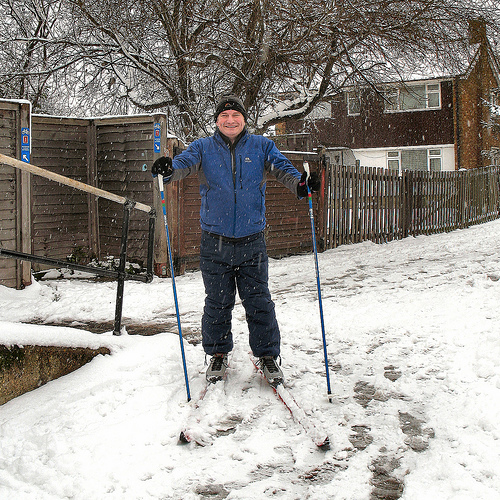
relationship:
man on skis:
[150, 96, 319, 384] [181, 383, 332, 449]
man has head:
[150, 96, 319, 384] [214, 94, 247, 136]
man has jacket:
[150, 96, 319, 384] [167, 131, 304, 234]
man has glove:
[150, 96, 319, 384] [150, 156, 177, 179]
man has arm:
[150, 96, 319, 384] [153, 139, 207, 184]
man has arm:
[150, 96, 319, 384] [264, 136, 324, 200]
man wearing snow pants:
[150, 96, 319, 384] [197, 229, 283, 358]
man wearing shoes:
[150, 96, 319, 384] [203, 353, 284, 384]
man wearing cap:
[150, 96, 319, 384] [214, 95, 250, 120]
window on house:
[385, 82, 439, 111] [271, 16, 500, 205]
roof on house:
[282, 38, 500, 87] [271, 16, 500, 205]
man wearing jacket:
[150, 96, 319, 384] [167, 131, 304, 234]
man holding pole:
[150, 96, 319, 384] [302, 160, 334, 407]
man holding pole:
[150, 96, 319, 384] [155, 174, 193, 405]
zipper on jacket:
[232, 180, 239, 238] [167, 131, 304, 234]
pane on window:
[399, 86, 426, 109] [385, 82, 439, 111]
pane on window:
[429, 92, 439, 108] [385, 82, 439, 111]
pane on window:
[385, 95, 395, 109] [385, 82, 439, 111]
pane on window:
[402, 150, 430, 175] [387, 146, 444, 171]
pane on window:
[430, 157, 441, 170] [387, 146, 444, 171]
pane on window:
[388, 160, 400, 169] [387, 146, 444, 171]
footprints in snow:
[347, 359, 433, 499] [1, 214, 500, 499]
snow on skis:
[194, 380, 225, 436] [181, 383, 332, 449]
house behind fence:
[271, 16, 500, 205] [325, 154, 500, 247]